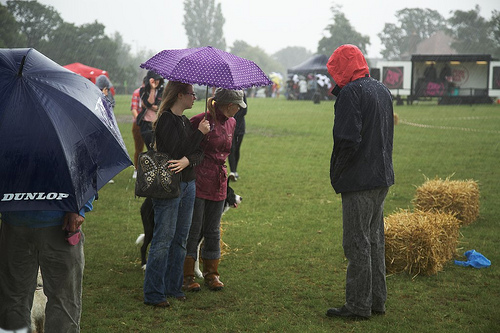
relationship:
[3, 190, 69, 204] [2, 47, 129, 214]
logo on umbrella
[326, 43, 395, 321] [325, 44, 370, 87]
person wearing hood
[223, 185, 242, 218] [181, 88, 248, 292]
dog behind woman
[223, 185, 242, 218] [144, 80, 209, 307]
dog behind woman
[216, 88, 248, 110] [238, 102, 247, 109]
cap has visor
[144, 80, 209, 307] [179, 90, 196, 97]
woman wearing eyeglasses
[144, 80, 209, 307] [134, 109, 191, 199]
woman holding handbag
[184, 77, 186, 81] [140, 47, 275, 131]
polka dot on umbrella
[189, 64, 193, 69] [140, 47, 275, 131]
polka dot on umbrella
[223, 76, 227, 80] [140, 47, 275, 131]
polka dot on umbrella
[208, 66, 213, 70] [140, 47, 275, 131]
polka dot on umbrella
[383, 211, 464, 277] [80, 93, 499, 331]
bale on field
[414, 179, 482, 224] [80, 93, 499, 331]
bale on field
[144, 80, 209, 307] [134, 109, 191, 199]
woman carrying handbag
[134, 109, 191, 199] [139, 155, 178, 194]
handbag has butterfly design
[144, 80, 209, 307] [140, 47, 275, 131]
woman holding umbrella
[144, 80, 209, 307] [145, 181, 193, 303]
woman wearing jeans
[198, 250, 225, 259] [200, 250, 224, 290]
trim on boot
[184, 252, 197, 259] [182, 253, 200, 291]
trim on boot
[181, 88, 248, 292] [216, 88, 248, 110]
woman wearing cap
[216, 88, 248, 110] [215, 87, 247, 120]
cap on head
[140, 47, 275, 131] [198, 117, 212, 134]
umbrella in hand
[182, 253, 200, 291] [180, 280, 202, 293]
boot on foot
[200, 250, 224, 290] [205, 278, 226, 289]
boot on foot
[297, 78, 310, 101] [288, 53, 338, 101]
person under tent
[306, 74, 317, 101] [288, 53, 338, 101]
person under tent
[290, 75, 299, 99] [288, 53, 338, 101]
person under tent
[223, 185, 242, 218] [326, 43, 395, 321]
dog near person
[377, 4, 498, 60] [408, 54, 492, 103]
trees behind stage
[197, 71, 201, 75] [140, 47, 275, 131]
polka dot on umbrella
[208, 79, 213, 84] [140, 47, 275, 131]
polka dot on umbrella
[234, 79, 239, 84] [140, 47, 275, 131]
polka dot on umbrella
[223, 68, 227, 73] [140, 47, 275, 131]
polka dot on umbrella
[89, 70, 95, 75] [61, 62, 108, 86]
dot on tent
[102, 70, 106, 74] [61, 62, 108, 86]
dot on tent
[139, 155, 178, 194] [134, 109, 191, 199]
butterfly design on handbag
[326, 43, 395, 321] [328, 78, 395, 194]
person wearing parka